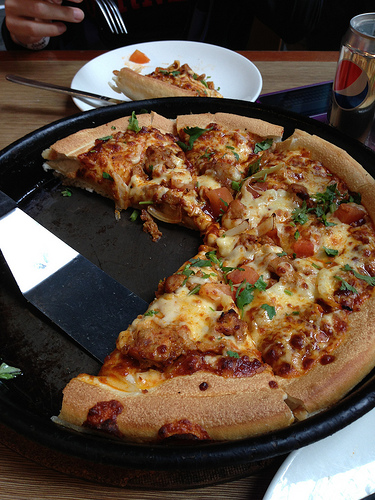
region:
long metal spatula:
[0, 193, 172, 369]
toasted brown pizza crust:
[69, 369, 289, 438]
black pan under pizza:
[0, 116, 332, 450]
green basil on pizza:
[150, 253, 275, 327]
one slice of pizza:
[66, 225, 284, 458]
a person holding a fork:
[2, 0, 196, 106]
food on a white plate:
[48, 35, 274, 113]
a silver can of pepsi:
[314, 0, 374, 142]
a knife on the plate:
[10, 65, 124, 109]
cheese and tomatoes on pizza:
[206, 219, 328, 318]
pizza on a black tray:
[138, 246, 238, 352]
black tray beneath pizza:
[117, 229, 164, 270]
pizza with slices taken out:
[89, 132, 319, 348]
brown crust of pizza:
[161, 379, 246, 437]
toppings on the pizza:
[227, 223, 310, 313]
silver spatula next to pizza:
[38, 207, 155, 343]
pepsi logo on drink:
[319, 51, 373, 108]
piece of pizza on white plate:
[141, 44, 231, 104]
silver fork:
[85, 2, 130, 51]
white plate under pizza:
[212, 38, 237, 78]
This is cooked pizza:
[51, 90, 355, 431]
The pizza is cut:
[11, 133, 352, 350]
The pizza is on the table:
[0, 409, 311, 494]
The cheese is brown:
[126, 307, 291, 451]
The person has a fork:
[8, 0, 158, 64]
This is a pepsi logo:
[319, 2, 372, 137]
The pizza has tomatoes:
[172, 217, 296, 338]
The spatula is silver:
[2, 188, 165, 385]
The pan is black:
[84, 221, 199, 292]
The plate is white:
[56, 15, 275, 171]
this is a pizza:
[205, 159, 334, 331]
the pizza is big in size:
[199, 165, 348, 421]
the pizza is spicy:
[221, 166, 339, 317]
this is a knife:
[65, 286, 118, 322]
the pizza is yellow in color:
[107, 130, 239, 201]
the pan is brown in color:
[103, 228, 136, 266]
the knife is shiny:
[17, 228, 47, 279]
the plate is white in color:
[218, 49, 245, 74]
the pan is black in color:
[13, 138, 33, 170]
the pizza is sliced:
[125, 261, 235, 423]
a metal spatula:
[0, 188, 154, 365]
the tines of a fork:
[96, 0, 130, 35]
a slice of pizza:
[38, 104, 214, 233]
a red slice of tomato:
[225, 263, 261, 286]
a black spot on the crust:
[78, 395, 126, 434]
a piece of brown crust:
[55, 371, 292, 444]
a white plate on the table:
[68, 40, 266, 114]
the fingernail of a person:
[70, 6, 86, 21]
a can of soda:
[325, 10, 373, 150]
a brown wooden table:
[0, 47, 360, 498]